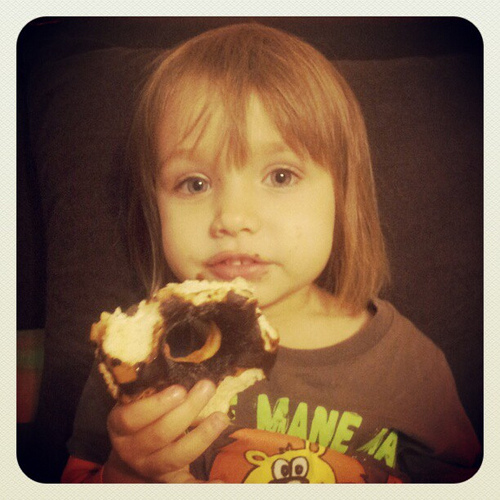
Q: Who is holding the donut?
A: A child.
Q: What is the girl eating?
A: A donut.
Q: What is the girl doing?
A: Eating a donut.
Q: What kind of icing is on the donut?
A: Chocolate.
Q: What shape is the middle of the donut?
A: Circle.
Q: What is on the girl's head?
A: Hair.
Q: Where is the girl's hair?
A: On her head.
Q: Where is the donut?
A: In the girl's hand.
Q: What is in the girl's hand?
A: A donut.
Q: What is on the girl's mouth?
A: Crumbs.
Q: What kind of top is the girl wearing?
A: A t-shirt.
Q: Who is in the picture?
A: A girl.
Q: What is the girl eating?
A: A donut.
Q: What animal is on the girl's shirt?
A: A lion.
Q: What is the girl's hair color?
A: Brown.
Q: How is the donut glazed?
A: With chocolate.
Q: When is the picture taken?
A: At breakfast time.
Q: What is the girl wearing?
A: A t shirt.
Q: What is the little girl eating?
A: A donut.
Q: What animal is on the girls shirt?
A: A lion.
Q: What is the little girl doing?
A: Eating a donut.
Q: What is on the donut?
A: Chocolate icing.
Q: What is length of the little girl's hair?
A: It's short.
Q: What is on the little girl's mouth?
A: Icing.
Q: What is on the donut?
A: Icing.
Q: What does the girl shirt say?
A: Mane.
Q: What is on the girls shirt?
A: A lion.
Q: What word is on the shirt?
A: Mane.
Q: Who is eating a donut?
A: A little girl.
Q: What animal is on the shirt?
A: Lion.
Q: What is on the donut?
A: Chocolate frosting.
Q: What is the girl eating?
A: Donut.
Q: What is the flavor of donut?
A: Chocolate.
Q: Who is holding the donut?
A: Girl.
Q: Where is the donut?
A: Girl's hands.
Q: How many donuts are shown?
A: One.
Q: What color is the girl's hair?
A: Red.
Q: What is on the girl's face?
A: Icing.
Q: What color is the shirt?
A: Black.